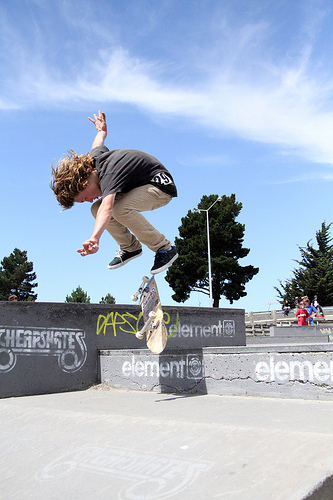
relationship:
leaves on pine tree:
[214, 212, 240, 271] [165, 193, 260, 309]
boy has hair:
[51, 109, 178, 275] [51, 149, 96, 210]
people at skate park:
[282, 295, 324, 324] [3, 263, 329, 496]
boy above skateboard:
[51, 109, 178, 275] [129, 273, 166, 354]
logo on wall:
[108, 345, 205, 398] [1, 311, 98, 388]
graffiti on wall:
[96, 311, 179, 338] [1, 298, 248, 402]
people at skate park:
[282, 295, 324, 324] [2, 283, 332, 498]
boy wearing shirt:
[292, 302, 311, 326] [296, 305, 310, 319]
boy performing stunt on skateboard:
[45, 104, 185, 271] [133, 270, 171, 358]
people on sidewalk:
[285, 293, 321, 335] [275, 320, 325, 332]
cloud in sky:
[0, 0, 333, 182] [0, 0, 330, 305]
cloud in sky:
[1, 4, 28, 116] [0, 0, 330, 305]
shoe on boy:
[150, 246, 178, 274] [47, 122, 214, 309]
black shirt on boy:
[90, 145, 177, 201] [51, 109, 178, 275]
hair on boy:
[42, 124, 85, 197] [39, 95, 230, 280]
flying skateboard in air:
[140, 275, 168, 354] [1, 0, 332, 301]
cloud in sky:
[0, 0, 333, 182] [51, 41, 290, 168]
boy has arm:
[51, 109, 178, 275] [82, 106, 108, 149]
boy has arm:
[51, 109, 178, 275] [72, 198, 119, 260]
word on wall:
[122, 353, 185, 380] [0, 298, 332, 402]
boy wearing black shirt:
[51, 109, 178, 275] [88, 146, 179, 205]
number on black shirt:
[148, 168, 174, 188] [88, 146, 179, 205]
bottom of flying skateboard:
[136, 279, 166, 349] [119, 262, 167, 353]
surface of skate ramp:
[1, 384, 332, 499] [94, 339, 221, 492]